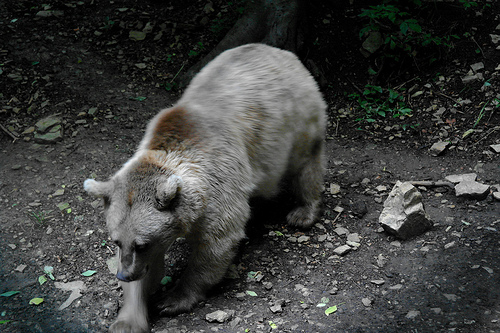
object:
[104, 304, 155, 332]
bear paw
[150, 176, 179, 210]
ear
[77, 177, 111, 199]
ear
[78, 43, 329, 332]
bear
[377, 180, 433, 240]
rock